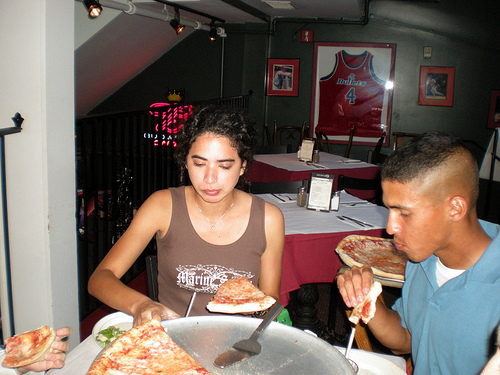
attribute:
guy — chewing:
[376, 148, 459, 281]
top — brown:
[153, 192, 266, 303]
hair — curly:
[163, 102, 258, 166]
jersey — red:
[316, 53, 392, 142]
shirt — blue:
[400, 245, 490, 341]